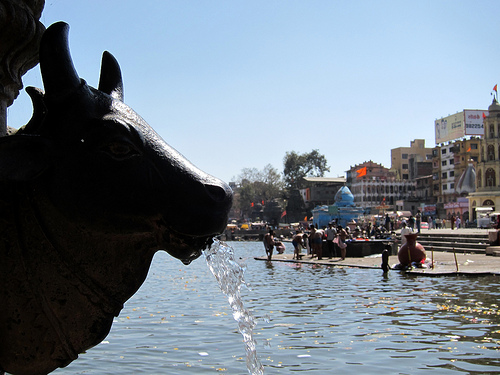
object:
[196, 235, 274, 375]
water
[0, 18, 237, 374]
statue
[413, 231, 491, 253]
steps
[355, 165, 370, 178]
flag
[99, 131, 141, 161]
eye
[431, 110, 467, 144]
billboard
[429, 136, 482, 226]
building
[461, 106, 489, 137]
billboard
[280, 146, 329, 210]
tree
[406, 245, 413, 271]
pole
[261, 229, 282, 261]
man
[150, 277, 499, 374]
water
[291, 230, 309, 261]
person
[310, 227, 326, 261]
person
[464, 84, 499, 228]
building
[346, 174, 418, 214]
building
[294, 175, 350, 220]
building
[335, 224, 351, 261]
person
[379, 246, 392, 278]
person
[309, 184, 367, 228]
building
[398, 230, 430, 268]
vase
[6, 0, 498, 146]
sky